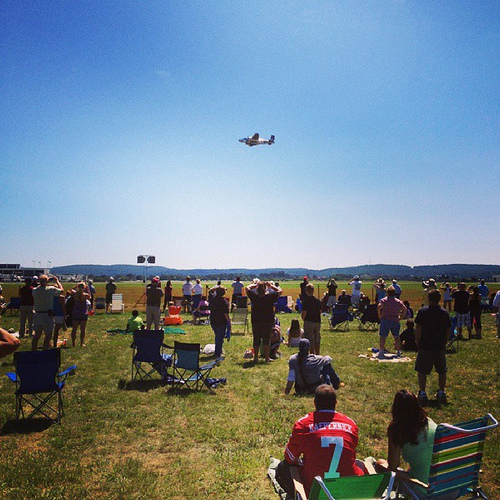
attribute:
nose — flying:
[237, 137, 247, 143]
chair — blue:
[1, 346, 83, 430]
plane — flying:
[234, 128, 274, 145]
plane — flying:
[237, 123, 276, 145]